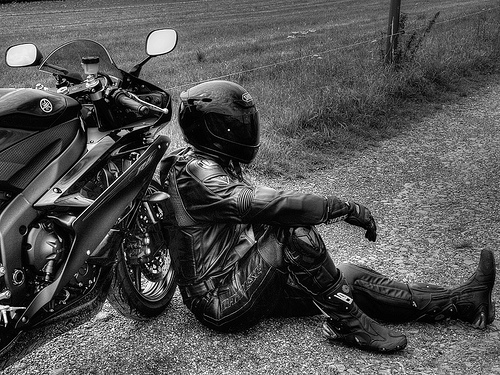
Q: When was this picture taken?
A: Daytime.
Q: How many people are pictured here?
A: One.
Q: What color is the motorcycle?
A: Black.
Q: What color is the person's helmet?
A: Black.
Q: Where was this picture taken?
A: A roadside.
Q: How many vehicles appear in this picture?
A: One.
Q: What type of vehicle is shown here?
A: Motorcycle.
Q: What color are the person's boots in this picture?
A: Black.